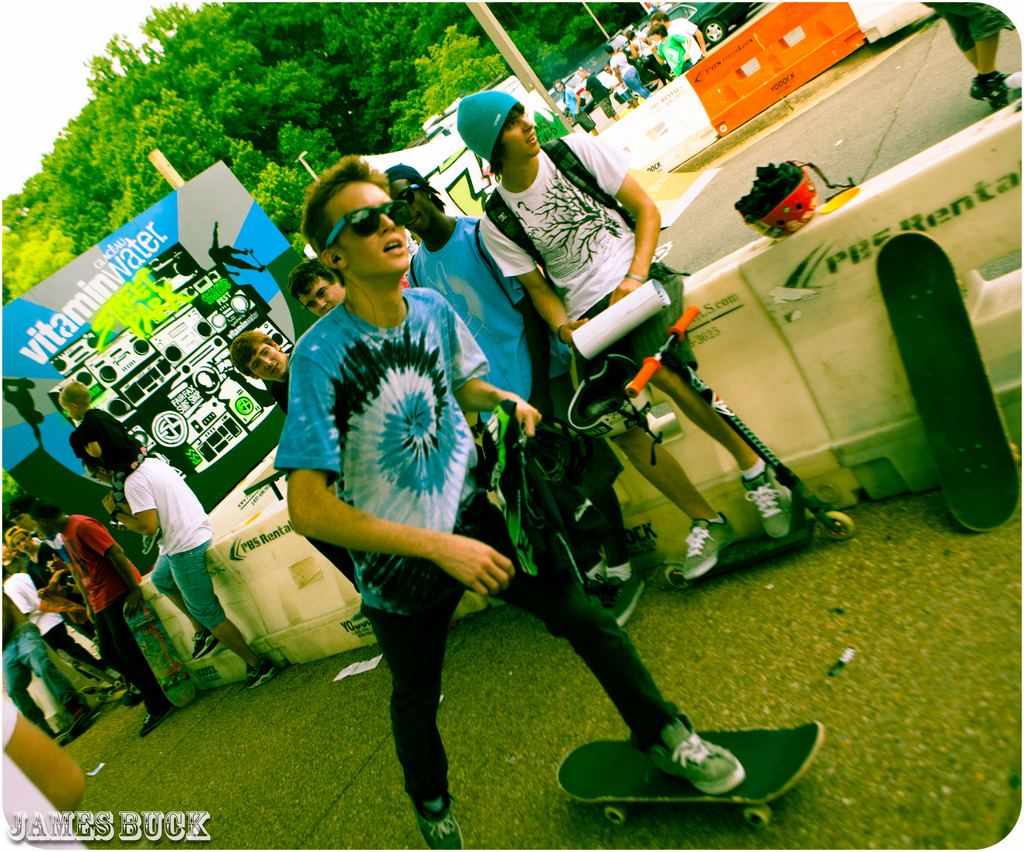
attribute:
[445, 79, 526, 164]
hat — blue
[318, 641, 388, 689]
paper — white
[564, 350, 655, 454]
helmet — white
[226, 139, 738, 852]
boy — riding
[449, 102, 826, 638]
boy — standing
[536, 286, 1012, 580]
wall — white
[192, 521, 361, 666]
wall — white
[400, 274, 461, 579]
shirt — black, white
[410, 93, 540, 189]
cap — blue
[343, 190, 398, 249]
sunglasses — black, blue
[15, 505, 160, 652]
shirt — red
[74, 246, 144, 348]
letters — white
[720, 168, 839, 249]
helmet — red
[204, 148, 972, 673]
wall — white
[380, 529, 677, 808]
jeans — black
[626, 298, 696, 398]
handles — red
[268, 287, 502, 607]
t-shirt — tie dyed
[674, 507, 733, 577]
shoe — green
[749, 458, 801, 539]
shoe — green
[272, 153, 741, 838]
man — young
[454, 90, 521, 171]
beanie cap — blue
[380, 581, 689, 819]
jeans — black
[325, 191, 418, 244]
sunglasses — blue and black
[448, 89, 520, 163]
cap — turquoise, stocking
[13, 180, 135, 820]
child — small